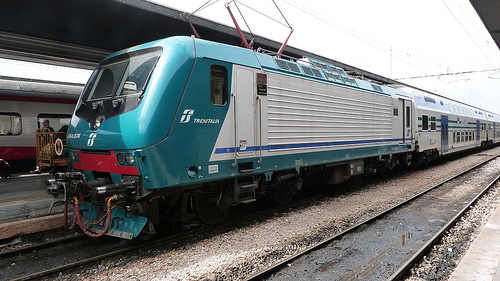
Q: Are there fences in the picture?
A: No, there are no fences.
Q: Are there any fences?
A: No, there are no fences.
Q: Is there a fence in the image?
A: No, there are no fences.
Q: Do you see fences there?
A: No, there are no fences.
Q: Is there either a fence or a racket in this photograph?
A: No, there are no fences or rackets.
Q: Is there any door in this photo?
A: Yes, there is a door.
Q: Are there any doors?
A: Yes, there is a door.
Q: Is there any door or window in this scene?
A: Yes, there is a door.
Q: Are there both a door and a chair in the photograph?
A: No, there is a door but no chairs.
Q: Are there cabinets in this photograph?
A: No, there are no cabinets.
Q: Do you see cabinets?
A: No, there are no cabinets.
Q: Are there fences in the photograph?
A: No, there are no fences.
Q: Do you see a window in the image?
A: Yes, there is a window.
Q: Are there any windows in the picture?
A: Yes, there is a window.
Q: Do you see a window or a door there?
A: Yes, there is a window.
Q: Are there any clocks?
A: No, there are no clocks.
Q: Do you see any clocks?
A: No, there are no clocks.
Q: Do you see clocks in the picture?
A: No, there are no clocks.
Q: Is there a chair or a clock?
A: No, there are no clocks or chairs.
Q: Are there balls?
A: No, there are no balls.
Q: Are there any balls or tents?
A: No, there are no balls or tents.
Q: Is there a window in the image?
A: Yes, there are windows.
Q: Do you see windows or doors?
A: Yes, there are windows.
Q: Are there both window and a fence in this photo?
A: No, there are windows but no fences.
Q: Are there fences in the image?
A: No, there are no fences.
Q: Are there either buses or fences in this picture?
A: No, there are no fences or buses.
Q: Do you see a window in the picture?
A: Yes, there is a window.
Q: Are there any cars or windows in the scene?
A: Yes, there is a window.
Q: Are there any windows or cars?
A: Yes, there is a window.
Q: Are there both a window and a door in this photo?
A: Yes, there are both a window and a door.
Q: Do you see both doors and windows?
A: Yes, there are both a window and a door.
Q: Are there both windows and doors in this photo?
A: Yes, there are both a window and a door.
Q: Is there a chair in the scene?
A: No, there are no chairs.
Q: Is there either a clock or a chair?
A: No, there are no chairs or clocks.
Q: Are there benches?
A: No, there are no benches.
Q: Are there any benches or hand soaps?
A: No, there are no benches or hand soaps.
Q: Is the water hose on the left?
A: Yes, the water hose is on the left of the image.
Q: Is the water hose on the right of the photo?
A: No, the water hose is on the left of the image.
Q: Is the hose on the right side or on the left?
A: The hose is on the left of the image.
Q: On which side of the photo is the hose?
A: The hose is on the left of the image.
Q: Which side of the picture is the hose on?
A: The hose is on the left of the image.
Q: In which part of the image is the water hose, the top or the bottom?
A: The water hose is in the bottom of the image.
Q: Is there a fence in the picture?
A: No, there are no fences.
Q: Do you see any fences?
A: No, there are no fences.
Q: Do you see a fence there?
A: No, there are no fences.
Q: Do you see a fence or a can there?
A: No, there are no fences or cans.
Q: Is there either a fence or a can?
A: No, there are no fences or cans.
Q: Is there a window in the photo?
A: Yes, there is a window.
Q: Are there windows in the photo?
A: Yes, there is a window.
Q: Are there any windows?
A: Yes, there is a window.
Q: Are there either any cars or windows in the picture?
A: Yes, there is a window.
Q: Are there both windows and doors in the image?
A: Yes, there are both a window and a door.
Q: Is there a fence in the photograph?
A: No, there are no fences.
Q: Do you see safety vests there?
A: No, there are no safety vests.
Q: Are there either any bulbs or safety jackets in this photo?
A: No, there are no safety jackets or bulbs.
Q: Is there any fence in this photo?
A: No, there are no fences.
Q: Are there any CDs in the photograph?
A: No, there are no cds.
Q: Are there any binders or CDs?
A: No, there are no CDs or binders.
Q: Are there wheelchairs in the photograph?
A: No, there are no wheelchairs.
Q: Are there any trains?
A: Yes, there is a train.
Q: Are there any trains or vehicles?
A: Yes, there is a train.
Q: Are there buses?
A: No, there are no buses.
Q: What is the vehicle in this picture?
A: The vehicle is a train.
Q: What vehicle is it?
A: The vehicle is a train.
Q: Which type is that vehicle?
A: This is a train.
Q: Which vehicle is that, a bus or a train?
A: This is a train.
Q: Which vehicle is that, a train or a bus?
A: This is a train.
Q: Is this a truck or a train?
A: This is a train.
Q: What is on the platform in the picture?
A: The train is on the platform.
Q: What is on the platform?
A: The train is on the platform.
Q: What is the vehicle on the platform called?
A: The vehicle is a train.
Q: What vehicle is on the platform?
A: The vehicle is a train.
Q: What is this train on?
A: The train is on the platform.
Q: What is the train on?
A: The train is on the platform.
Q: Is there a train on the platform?
A: Yes, there is a train on the platform.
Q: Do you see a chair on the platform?
A: No, there is a train on the platform.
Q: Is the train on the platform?
A: Yes, the train is on the platform.